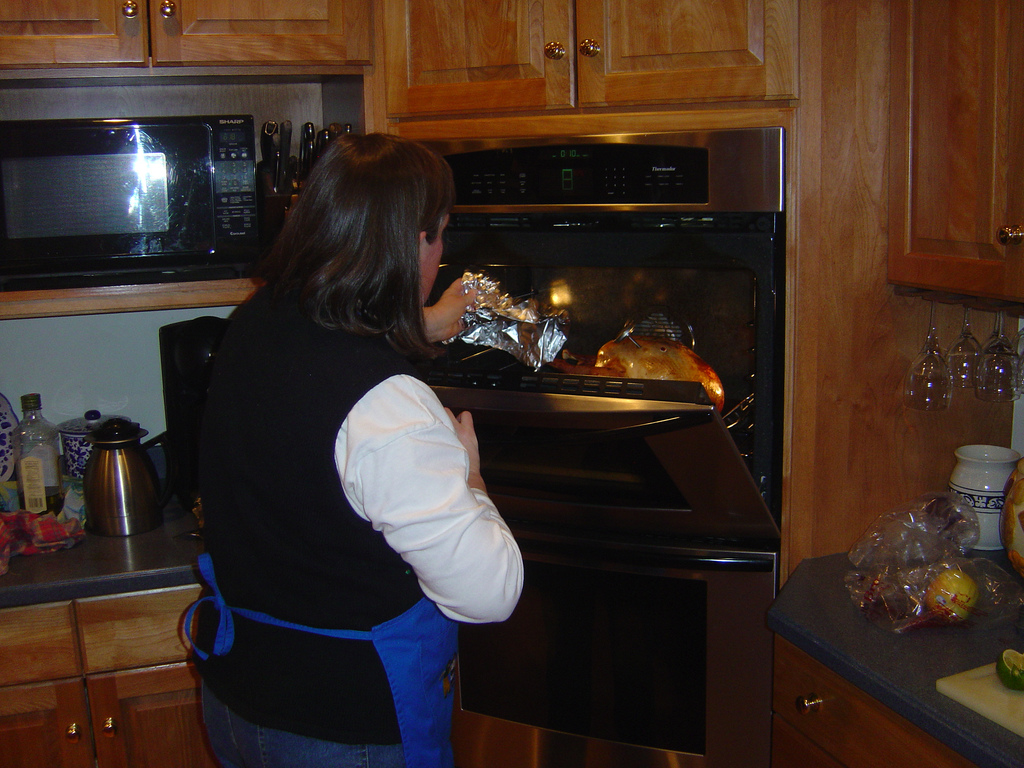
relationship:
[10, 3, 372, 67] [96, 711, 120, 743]
cabinet with handle